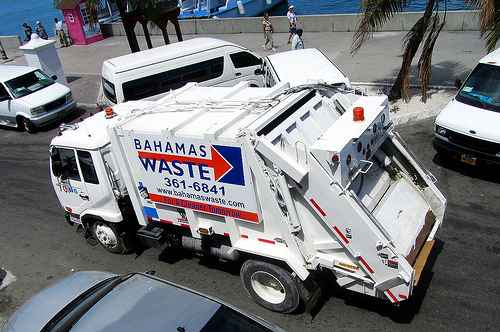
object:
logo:
[132, 138, 246, 187]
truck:
[48, 78, 450, 315]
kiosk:
[58, 0, 107, 46]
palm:
[347, 0, 451, 101]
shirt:
[286, 10, 298, 29]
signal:
[105, 107, 118, 119]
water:
[0, 1, 491, 40]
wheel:
[239, 255, 301, 315]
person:
[261, 11, 278, 53]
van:
[1, 64, 80, 134]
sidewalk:
[0, 31, 500, 87]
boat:
[175, 0, 293, 19]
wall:
[101, 9, 494, 38]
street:
[0, 105, 499, 331]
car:
[1, 268, 288, 331]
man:
[285, 4, 303, 44]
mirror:
[51, 146, 65, 178]